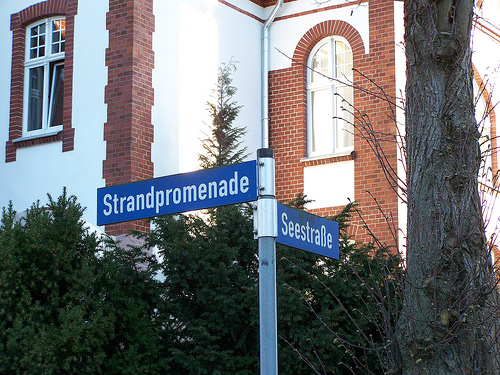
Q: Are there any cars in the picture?
A: No, there are no cars.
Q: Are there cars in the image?
A: No, there are no cars.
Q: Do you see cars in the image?
A: No, there are no cars.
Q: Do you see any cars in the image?
A: No, there are no cars.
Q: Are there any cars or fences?
A: No, there are no cars or fences.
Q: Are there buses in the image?
A: No, there are no buses.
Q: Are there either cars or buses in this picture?
A: No, there are no buses or cars.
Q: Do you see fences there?
A: No, there are no fences.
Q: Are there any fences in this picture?
A: No, there are no fences.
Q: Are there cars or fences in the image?
A: No, there are no fences or cars.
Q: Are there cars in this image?
A: No, there are no cars.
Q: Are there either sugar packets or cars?
A: No, there are no cars or sugar packets.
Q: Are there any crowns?
A: No, there are no crowns.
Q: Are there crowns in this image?
A: No, there are no crowns.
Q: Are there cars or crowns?
A: No, there are no crowns or cars.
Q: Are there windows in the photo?
A: Yes, there is a window.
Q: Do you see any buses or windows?
A: Yes, there is a window.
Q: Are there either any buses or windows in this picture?
A: Yes, there is a window.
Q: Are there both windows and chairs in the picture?
A: No, there is a window but no chairs.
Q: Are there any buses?
A: No, there are no buses.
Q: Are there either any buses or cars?
A: No, there are no buses or cars.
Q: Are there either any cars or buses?
A: No, there are no buses or cars.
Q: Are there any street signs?
A: Yes, there is a street sign.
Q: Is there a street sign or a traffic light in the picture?
A: Yes, there is a street sign.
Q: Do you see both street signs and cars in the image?
A: No, there is a street sign but no cars.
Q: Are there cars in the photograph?
A: No, there are no cars.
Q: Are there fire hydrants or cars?
A: No, there are no cars or fire hydrants.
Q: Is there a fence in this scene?
A: No, there are no fences.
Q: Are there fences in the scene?
A: No, there are no fences.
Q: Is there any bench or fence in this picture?
A: No, there are no fences or benches.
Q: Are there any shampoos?
A: No, there are no shampoos.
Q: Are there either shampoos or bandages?
A: No, there are no shampoos or bandages.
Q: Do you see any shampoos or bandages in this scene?
A: No, there are no shampoos or bandages.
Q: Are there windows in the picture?
A: Yes, there are windows.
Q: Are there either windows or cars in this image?
A: Yes, there are windows.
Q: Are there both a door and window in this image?
A: No, there are windows but no doors.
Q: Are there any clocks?
A: No, there are no clocks.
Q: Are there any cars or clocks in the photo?
A: No, there are no clocks or cars.